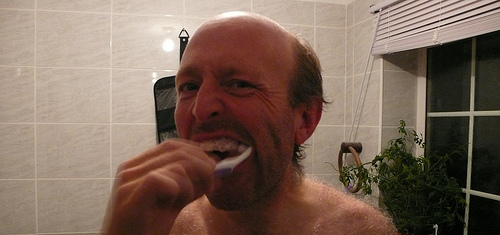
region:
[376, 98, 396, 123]
edge of a wa;;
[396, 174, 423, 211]
part of a plant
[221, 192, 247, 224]
edge of a chin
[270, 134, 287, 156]
part of a cheek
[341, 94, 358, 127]
part of a corner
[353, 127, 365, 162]
part of a handle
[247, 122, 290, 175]
part of a cheel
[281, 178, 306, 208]
part of a neck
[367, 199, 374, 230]
[art of a shoulser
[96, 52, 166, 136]
par tof a wall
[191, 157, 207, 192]
part of a finger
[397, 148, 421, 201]
part of a plant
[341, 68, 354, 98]
part of a corner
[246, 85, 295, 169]
part of a cheek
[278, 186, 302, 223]
part of a neck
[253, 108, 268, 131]
part of a cheek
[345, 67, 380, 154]
par of a rope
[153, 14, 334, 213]
a man brushing his teeth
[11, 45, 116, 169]
white marble tiles of the wall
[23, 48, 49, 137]
white grout in between the tiles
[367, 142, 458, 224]
green plant growing on the window sill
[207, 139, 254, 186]
a white toothbrush with a purple handle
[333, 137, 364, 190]
brown wood towel ring on the wall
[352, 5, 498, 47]
white shades on the window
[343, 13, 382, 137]
white plastic rod of the shades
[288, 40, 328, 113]
short black hair on the man's head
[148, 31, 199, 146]
a black and grey toiletry case hung on the wall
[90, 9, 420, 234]
this man is brushing his teeth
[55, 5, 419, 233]
this guy looks rough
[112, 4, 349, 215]
he is a middle aged man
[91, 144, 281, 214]
his hand is holding a toothbrush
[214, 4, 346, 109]
he is balding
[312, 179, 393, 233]
he has a hairy shoulder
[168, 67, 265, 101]
his eyes look intense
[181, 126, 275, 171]
his mouth is full of toothpaste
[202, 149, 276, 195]
his toothbrush is white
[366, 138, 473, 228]
plants are behind the man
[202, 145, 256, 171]
The toothbrush in the man's mouth.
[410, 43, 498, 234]
The window in the room.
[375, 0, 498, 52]
The venetian blind on the window.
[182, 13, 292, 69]
The bald head of the man.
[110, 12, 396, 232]
a man with toothbrush in mouth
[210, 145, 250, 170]
a white and purple toothbrush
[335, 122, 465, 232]
a green plant by the window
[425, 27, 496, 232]
a bathroom window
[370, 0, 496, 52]
white mini-blinds on the window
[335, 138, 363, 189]
a round brown towel rack on wall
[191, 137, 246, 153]
the man's top teeth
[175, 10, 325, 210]
the man's balding head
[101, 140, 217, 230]
the man's hand holding a toothbrush